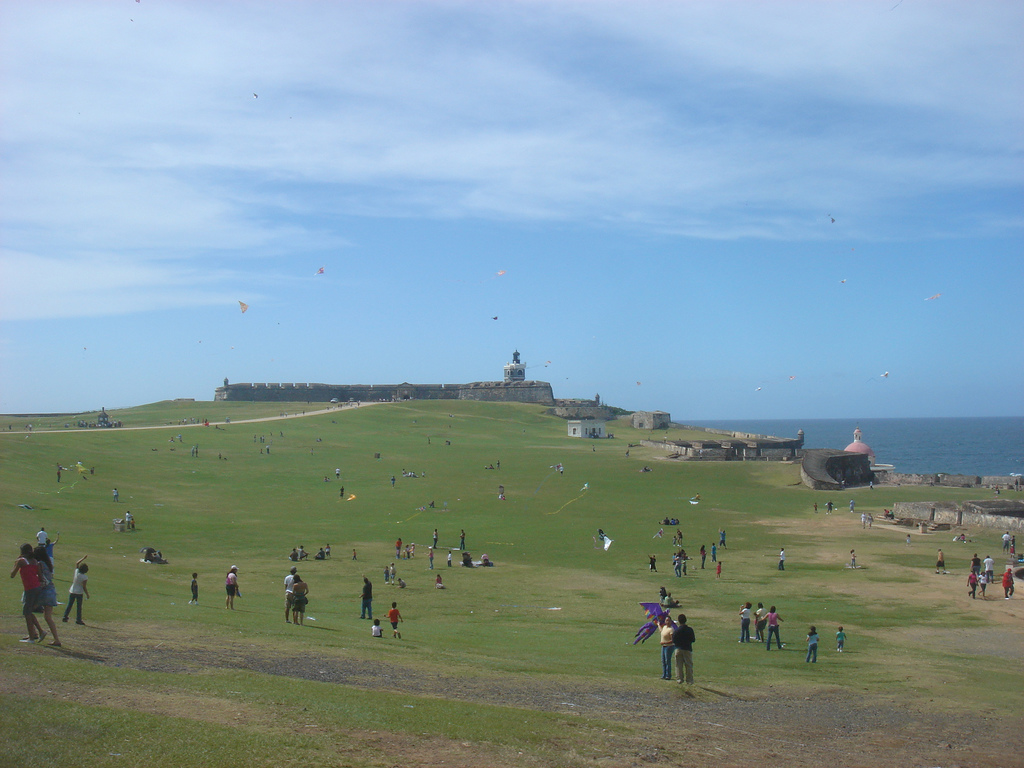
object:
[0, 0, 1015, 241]
clouds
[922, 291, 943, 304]
kites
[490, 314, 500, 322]
kites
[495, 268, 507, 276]
kites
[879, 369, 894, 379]
kites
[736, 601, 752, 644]
person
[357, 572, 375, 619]
person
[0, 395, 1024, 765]
field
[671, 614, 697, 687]
person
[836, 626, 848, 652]
person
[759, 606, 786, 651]
person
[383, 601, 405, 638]
person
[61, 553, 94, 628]
person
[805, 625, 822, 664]
person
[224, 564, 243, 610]
person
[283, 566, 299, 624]
person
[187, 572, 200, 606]
person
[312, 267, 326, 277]
kites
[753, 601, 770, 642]
person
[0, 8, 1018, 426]
sky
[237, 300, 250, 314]
kites